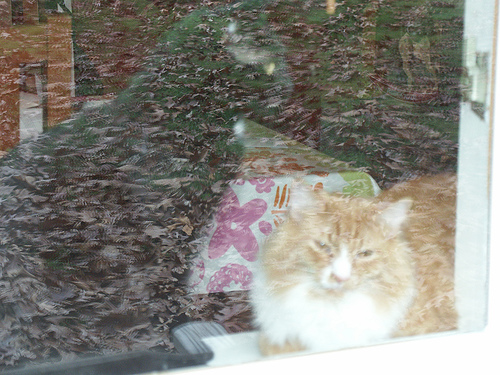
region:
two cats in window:
[34, 11, 449, 370]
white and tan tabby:
[249, 190, 440, 361]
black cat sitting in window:
[6, 12, 346, 348]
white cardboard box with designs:
[224, 127, 372, 319]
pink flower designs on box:
[227, 174, 283, 270]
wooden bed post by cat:
[32, 15, 95, 112]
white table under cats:
[169, 328, 301, 368]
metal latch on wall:
[431, 44, 497, 126]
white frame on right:
[449, 25, 499, 271]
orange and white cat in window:
[251, 180, 492, 359]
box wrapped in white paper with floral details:
[155, 117, 326, 286]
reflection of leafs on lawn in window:
[13, 134, 168, 324]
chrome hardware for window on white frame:
[448, 33, 489, 135]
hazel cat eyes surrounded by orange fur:
[307, 230, 380, 262]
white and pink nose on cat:
[326, 263, 358, 297]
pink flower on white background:
[201, 175, 262, 272]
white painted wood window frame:
[450, 0, 489, 265]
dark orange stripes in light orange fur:
[330, 210, 364, 251]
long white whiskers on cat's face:
[271, 255, 330, 296]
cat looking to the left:
[255, 199, 412, 331]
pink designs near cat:
[195, 185, 252, 287]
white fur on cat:
[248, 280, 394, 345]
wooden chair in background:
[0, 28, 67, 125]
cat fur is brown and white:
[278, 182, 457, 336]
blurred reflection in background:
[377, 13, 439, 115]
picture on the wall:
[6, 71, 46, 94]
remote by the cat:
[176, 318, 226, 352]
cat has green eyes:
[297, 239, 374, 266]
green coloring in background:
[134, 27, 473, 146]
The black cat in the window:
[1, 0, 291, 372]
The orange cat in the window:
[228, 158, 458, 352]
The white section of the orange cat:
[252, 250, 413, 345]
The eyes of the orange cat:
[316, 231, 374, 263]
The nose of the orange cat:
[326, 261, 361, 297]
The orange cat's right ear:
[282, 170, 328, 227]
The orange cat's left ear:
[370, 190, 423, 246]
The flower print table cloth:
[194, 115, 386, 302]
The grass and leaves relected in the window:
[1, 0, 462, 373]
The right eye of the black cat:
[259, 54, 279, 80]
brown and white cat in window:
[231, 182, 475, 339]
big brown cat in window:
[224, 184, 471, 337]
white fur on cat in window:
[262, 287, 379, 345]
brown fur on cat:
[377, 184, 459, 274]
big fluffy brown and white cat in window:
[252, 179, 475, 346]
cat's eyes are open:
[307, 232, 379, 264]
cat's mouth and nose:
[319, 258, 354, 293]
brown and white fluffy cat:
[248, 171, 475, 347]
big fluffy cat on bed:
[249, 166, 465, 340]